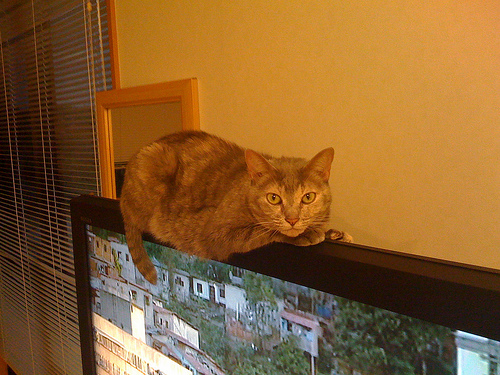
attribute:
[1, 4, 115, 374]
blinds — white, venetian, old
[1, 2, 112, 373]
window — closed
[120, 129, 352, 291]
cat — gray, white, staring, angry, awake, sitting, orange, striped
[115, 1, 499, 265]
wall — yellow, painted, white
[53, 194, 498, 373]
television — on, black, flat, big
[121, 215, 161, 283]
tail — striped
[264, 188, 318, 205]
eye — golden